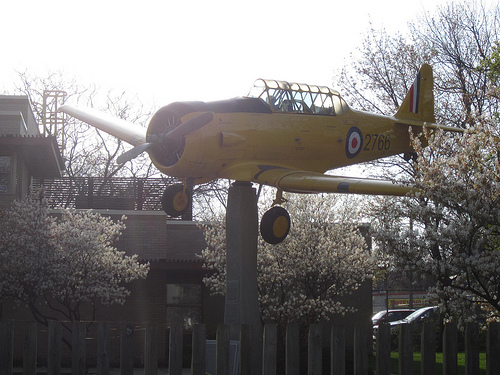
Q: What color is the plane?
A: Yellow.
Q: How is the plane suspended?
A: Column.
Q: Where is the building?
A: Background.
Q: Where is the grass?
A: By vehicles.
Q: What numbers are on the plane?
A: 2766.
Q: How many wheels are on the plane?
A: Two.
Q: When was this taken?
A: Daytime.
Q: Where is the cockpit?
A: Top.